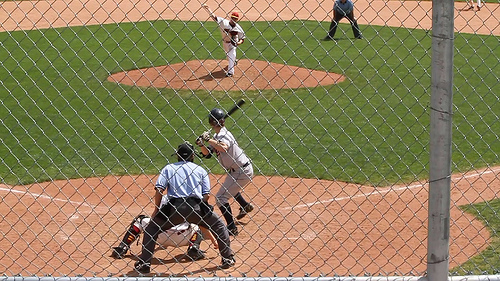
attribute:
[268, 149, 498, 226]
line — white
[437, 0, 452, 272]
pole — metal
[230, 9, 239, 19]
hat — red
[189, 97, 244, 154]
bat — black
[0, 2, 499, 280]
fence — metal